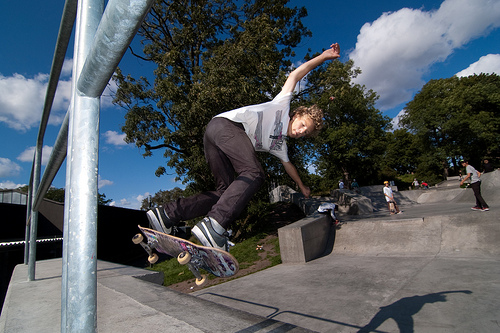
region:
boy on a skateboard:
[113, 38, 418, 289]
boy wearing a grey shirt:
[126, 40, 343, 292]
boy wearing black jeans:
[125, 37, 350, 277]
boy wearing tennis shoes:
[132, 40, 364, 286]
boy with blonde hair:
[121, 36, 363, 291]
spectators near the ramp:
[350, 144, 497, 242]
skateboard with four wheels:
[126, 225, 246, 290]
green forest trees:
[318, 60, 497, 172]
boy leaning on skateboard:
[118, 33, 380, 302]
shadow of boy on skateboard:
[339, 266, 498, 331]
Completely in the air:
[129, 35, 376, 305]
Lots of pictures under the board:
[120, 220, 247, 287]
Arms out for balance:
[171, 25, 354, 276]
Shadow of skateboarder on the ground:
[324, 263, 489, 331]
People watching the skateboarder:
[371, 155, 496, 232]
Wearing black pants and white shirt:
[153, 76, 298, 261]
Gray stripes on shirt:
[234, 85, 300, 176]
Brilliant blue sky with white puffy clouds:
[344, 1, 499, 97]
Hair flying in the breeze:
[276, 74, 334, 169]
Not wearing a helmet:
[275, 85, 337, 155]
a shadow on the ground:
[357, 288, 474, 332]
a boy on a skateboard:
[128, 38, 342, 288]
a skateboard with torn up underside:
[128, 222, 240, 287]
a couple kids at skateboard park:
[373, 154, 492, 229]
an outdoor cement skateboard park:
[332, 168, 499, 253]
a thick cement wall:
[266, 183, 338, 267]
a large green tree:
[389, 74, 499, 183]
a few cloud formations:
[2, 52, 129, 193]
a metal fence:
[19, 0, 154, 331]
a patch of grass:
[133, 216, 294, 301]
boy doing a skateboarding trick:
[126, 35, 360, 277]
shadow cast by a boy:
[353, 278, 474, 331]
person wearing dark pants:
[456, 159, 491, 216]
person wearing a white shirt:
[380, 182, 401, 214]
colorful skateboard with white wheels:
[131, 223, 235, 284]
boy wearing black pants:
[137, 48, 339, 278]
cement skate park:
[54, 173, 493, 330]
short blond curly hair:
[294, 99, 325, 136]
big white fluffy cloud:
[339, 0, 499, 116]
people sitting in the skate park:
[330, 175, 360, 208]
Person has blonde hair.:
[286, 101, 340, 141]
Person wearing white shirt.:
[251, 87, 297, 182]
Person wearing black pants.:
[191, 113, 250, 248]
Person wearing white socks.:
[152, 199, 249, 244]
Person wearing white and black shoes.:
[146, 203, 246, 260]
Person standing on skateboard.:
[132, 188, 254, 288]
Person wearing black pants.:
[463, 186, 483, 199]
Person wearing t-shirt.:
[459, 157, 483, 182]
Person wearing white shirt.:
[378, 182, 395, 202]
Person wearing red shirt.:
[419, 179, 429, 189]